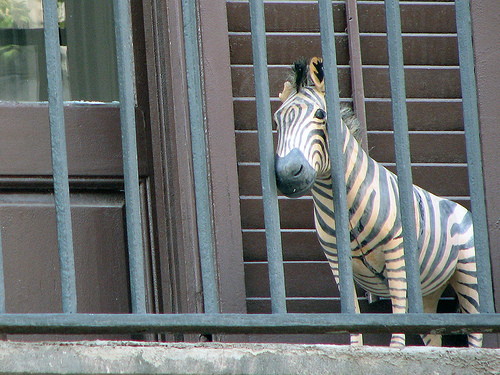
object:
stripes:
[273, 85, 482, 350]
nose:
[269, 148, 322, 197]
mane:
[288, 58, 309, 94]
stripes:
[346, 146, 364, 194]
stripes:
[349, 155, 376, 220]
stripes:
[419, 190, 436, 281]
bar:
[317, 0, 355, 312]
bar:
[248, 0, 287, 312]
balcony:
[0, 340, 497, 373]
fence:
[1, 0, 496, 335]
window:
[2, 1, 141, 104]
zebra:
[272, 54, 482, 350]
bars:
[6, 9, 458, 325]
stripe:
[366, 166, 407, 246]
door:
[4, 0, 168, 340]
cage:
[0, 0, 498, 373]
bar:
[383, 2, 425, 314]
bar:
[455, 0, 496, 309]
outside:
[2, 2, 482, 369]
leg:
[382, 237, 408, 347]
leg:
[453, 249, 483, 348]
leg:
[415, 281, 447, 345]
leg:
[330, 258, 362, 342]